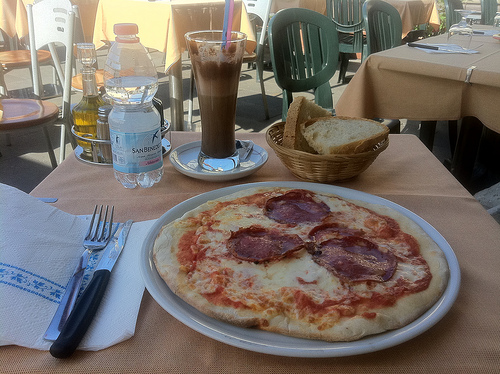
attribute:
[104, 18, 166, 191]
bottle — plastic